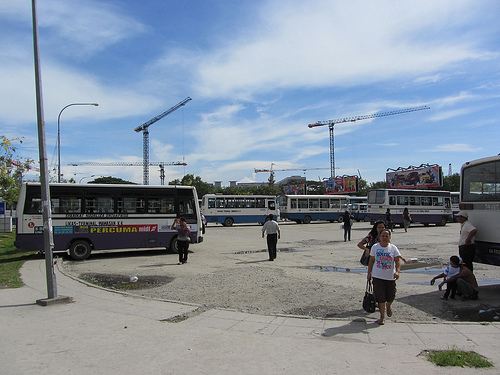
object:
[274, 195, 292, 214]
window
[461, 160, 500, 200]
window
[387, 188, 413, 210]
window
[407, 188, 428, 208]
window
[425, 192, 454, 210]
window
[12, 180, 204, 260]
bus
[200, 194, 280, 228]
bus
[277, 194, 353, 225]
bus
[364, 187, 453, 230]
bus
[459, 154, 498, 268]
bus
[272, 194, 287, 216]
bus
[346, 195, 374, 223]
bus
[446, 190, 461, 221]
bus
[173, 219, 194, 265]
people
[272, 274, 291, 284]
lot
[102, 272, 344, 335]
curb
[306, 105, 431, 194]
cranes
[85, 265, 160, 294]
spot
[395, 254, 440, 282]
water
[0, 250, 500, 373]
sidewalk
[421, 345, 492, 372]
patch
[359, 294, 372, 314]
purse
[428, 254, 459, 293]
child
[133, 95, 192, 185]
cranes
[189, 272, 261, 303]
lot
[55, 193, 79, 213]
window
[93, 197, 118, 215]
window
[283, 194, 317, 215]
window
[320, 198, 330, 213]
window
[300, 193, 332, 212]
window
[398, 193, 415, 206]
window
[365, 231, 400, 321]
person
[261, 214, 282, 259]
man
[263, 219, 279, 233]
shirt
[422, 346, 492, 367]
grass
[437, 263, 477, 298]
boy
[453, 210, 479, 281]
man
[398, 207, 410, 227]
person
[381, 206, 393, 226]
person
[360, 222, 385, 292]
woman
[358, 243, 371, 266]
purse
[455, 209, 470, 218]
hat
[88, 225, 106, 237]
letter